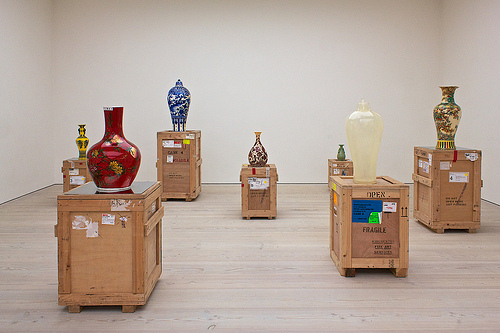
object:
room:
[0, 2, 500, 332]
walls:
[2, 0, 499, 218]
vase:
[345, 99, 381, 181]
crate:
[327, 173, 412, 276]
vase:
[165, 76, 194, 133]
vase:
[80, 106, 140, 196]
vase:
[76, 123, 91, 163]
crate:
[154, 127, 204, 203]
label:
[363, 209, 385, 225]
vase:
[336, 141, 349, 162]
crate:
[326, 158, 357, 179]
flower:
[90, 146, 103, 159]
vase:
[430, 83, 459, 151]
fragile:
[361, 225, 389, 237]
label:
[378, 199, 401, 215]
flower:
[106, 161, 124, 173]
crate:
[59, 157, 93, 200]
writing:
[361, 188, 391, 201]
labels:
[70, 213, 101, 238]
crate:
[51, 176, 170, 314]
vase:
[248, 130, 270, 169]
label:
[349, 197, 384, 225]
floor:
[0, 182, 499, 332]